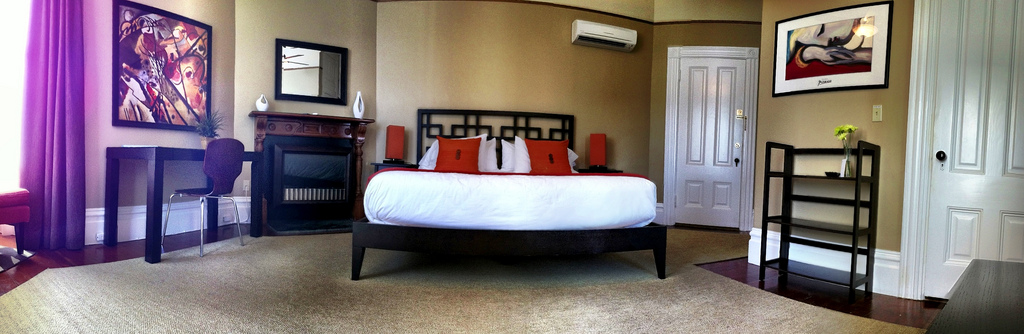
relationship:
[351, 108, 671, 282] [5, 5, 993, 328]
bed standing inside room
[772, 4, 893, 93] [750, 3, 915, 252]
artwork hanging on wall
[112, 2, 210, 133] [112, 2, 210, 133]
picture in picture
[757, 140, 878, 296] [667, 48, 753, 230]
shelf by door